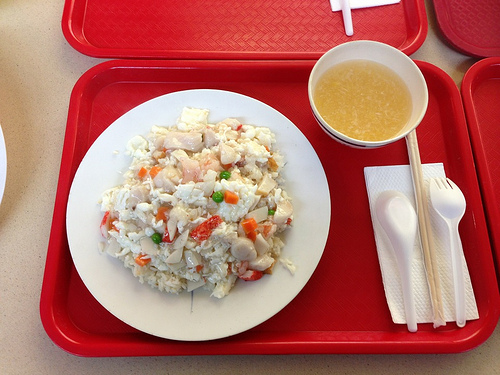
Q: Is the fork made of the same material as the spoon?
A: Yes, both the fork and the spoon are made of plastic.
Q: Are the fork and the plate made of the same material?
A: Yes, both the fork and the plate are made of plastic.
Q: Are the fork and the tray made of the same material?
A: Yes, both the fork and the tray are made of plastic.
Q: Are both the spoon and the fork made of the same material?
A: Yes, both the spoon and the fork are made of plastic.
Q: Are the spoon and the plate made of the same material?
A: Yes, both the spoon and the plate are made of plastic.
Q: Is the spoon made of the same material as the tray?
A: Yes, both the spoon and the tray are made of plastic.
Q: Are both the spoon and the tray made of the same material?
A: Yes, both the spoon and the tray are made of plastic.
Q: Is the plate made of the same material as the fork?
A: Yes, both the plate and the fork are made of plastic.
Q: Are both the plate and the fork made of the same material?
A: Yes, both the plate and the fork are made of plastic.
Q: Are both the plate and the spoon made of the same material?
A: Yes, both the plate and the spoon are made of plastic.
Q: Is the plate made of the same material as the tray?
A: Yes, both the plate and the tray are made of plastic.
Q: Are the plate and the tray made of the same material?
A: Yes, both the plate and the tray are made of plastic.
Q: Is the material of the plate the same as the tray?
A: Yes, both the plate and the tray are made of plastic.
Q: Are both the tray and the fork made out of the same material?
A: Yes, both the tray and the fork are made of plastic.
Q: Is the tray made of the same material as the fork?
A: Yes, both the tray and the fork are made of plastic.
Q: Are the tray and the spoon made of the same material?
A: Yes, both the tray and the spoon are made of plastic.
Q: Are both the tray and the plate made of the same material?
A: Yes, both the tray and the plate are made of plastic.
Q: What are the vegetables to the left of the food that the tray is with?
A: The vegetables are peas.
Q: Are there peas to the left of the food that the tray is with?
A: Yes, there are peas to the left of the food.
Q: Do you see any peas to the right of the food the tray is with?
A: No, the peas are to the left of the food.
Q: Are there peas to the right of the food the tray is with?
A: No, the peas are to the left of the food.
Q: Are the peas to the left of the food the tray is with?
A: Yes, the peas are to the left of the food.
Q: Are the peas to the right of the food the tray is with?
A: No, the peas are to the left of the food.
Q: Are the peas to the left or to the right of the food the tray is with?
A: The peas are to the left of the food.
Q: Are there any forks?
A: Yes, there is a fork.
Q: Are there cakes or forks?
A: Yes, there is a fork.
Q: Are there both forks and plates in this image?
A: Yes, there are both a fork and a plate.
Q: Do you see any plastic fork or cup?
A: Yes, there is a plastic fork.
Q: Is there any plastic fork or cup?
A: Yes, there is a plastic fork.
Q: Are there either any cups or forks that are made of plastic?
A: Yes, the fork is made of plastic.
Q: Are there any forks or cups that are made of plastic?
A: Yes, the fork is made of plastic.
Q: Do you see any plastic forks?
A: Yes, there is a fork that is made of plastic.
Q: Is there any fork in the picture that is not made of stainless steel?
A: Yes, there is a fork that is made of plastic.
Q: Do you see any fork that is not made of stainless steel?
A: Yes, there is a fork that is made of plastic.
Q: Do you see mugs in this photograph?
A: No, there are no mugs.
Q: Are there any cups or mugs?
A: No, there are no mugs or cups.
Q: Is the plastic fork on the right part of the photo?
A: Yes, the fork is on the right of the image.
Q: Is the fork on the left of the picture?
A: No, the fork is on the right of the image.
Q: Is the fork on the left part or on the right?
A: The fork is on the right of the image.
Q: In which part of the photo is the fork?
A: The fork is on the right of the image.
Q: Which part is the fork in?
A: The fork is on the right of the image.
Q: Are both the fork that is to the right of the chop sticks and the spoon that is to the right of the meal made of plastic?
A: Yes, both the fork and the spoon are made of plastic.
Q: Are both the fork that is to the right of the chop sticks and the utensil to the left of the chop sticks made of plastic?
A: Yes, both the fork and the spoon are made of plastic.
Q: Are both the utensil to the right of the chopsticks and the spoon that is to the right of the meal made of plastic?
A: Yes, both the fork and the spoon are made of plastic.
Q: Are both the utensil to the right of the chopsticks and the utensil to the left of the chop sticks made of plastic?
A: Yes, both the fork and the spoon are made of plastic.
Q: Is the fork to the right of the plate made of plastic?
A: Yes, the fork is made of plastic.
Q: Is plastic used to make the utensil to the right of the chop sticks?
A: Yes, the fork is made of plastic.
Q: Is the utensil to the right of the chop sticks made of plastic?
A: Yes, the fork is made of plastic.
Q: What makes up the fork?
A: The fork is made of plastic.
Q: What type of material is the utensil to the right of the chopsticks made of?
A: The fork is made of plastic.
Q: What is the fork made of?
A: The fork is made of plastic.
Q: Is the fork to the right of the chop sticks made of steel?
A: No, the fork is made of plastic.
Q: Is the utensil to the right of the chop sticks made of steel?
A: No, the fork is made of plastic.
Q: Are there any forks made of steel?
A: No, there is a fork but it is made of plastic.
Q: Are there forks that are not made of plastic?
A: No, there is a fork but it is made of plastic.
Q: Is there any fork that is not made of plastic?
A: No, there is a fork but it is made of plastic.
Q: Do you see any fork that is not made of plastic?
A: No, there is a fork but it is made of plastic.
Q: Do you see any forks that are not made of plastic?
A: No, there is a fork but it is made of plastic.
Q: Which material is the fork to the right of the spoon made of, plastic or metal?
A: The fork is made of plastic.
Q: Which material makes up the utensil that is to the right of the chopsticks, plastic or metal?
A: The fork is made of plastic.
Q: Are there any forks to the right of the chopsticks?
A: Yes, there is a fork to the right of the chopsticks.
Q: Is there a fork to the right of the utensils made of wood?
A: Yes, there is a fork to the right of the chopsticks.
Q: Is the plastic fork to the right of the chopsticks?
A: Yes, the fork is to the right of the chopsticks.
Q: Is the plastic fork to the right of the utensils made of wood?
A: Yes, the fork is to the right of the chopsticks.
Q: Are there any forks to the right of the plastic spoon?
A: Yes, there is a fork to the right of the spoon.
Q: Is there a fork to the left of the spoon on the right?
A: No, the fork is to the right of the spoon.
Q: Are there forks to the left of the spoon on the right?
A: No, the fork is to the right of the spoon.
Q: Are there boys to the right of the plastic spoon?
A: No, there is a fork to the right of the spoon.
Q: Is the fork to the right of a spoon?
A: Yes, the fork is to the right of a spoon.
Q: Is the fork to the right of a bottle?
A: No, the fork is to the right of a spoon.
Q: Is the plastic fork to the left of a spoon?
A: No, the fork is to the right of a spoon.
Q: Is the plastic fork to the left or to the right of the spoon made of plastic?
A: The fork is to the right of the spoon.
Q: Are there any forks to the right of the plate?
A: Yes, there is a fork to the right of the plate.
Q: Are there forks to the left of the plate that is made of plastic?
A: No, the fork is to the right of the plate.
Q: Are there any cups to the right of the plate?
A: No, there is a fork to the right of the plate.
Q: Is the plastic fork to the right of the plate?
A: Yes, the fork is to the right of the plate.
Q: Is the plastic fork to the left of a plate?
A: No, the fork is to the right of a plate.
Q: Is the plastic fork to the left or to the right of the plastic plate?
A: The fork is to the right of the plate.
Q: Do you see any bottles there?
A: No, there are no bottles.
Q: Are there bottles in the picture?
A: No, there are no bottles.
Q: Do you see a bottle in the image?
A: No, there are no bottles.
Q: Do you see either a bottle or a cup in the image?
A: No, there are no bottles or cups.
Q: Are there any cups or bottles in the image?
A: No, there are no bottles or cups.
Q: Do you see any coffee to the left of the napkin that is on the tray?
A: No, there is meal to the left of the napkin.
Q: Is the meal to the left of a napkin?
A: Yes, the meal is to the left of a napkin.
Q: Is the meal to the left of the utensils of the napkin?
A: Yes, the meal is to the left of the utensils.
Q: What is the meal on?
A: The meal is on the tray.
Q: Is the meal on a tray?
A: Yes, the meal is on a tray.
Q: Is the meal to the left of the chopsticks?
A: Yes, the meal is to the left of the chopsticks.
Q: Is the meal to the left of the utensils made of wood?
A: Yes, the meal is to the left of the chopsticks.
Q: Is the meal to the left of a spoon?
A: Yes, the meal is to the left of a spoon.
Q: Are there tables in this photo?
A: Yes, there is a table.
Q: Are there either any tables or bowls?
A: Yes, there is a table.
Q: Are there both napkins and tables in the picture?
A: Yes, there are both a table and a napkin.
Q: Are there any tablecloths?
A: No, there are no tablecloths.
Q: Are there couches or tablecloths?
A: No, there are no tablecloths or couches.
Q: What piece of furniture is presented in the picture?
A: The piece of furniture is a table.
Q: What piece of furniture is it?
A: The piece of furniture is a table.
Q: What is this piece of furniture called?
A: This is a table.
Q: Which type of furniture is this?
A: This is a table.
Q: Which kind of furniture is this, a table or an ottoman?
A: This is a table.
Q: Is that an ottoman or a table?
A: That is a table.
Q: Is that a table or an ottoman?
A: That is a table.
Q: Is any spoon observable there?
A: Yes, there is a spoon.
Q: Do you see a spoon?
A: Yes, there is a spoon.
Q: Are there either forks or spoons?
A: Yes, there is a spoon.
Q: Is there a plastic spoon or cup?
A: Yes, there is a plastic spoon.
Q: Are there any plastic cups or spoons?
A: Yes, there is a plastic spoon.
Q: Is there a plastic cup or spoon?
A: Yes, there is a plastic spoon.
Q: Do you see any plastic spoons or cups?
A: Yes, there is a plastic spoon.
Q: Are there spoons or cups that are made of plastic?
A: Yes, the spoon is made of plastic.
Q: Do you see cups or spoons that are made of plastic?
A: Yes, the spoon is made of plastic.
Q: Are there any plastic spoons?
A: Yes, there is a spoon that is made of plastic.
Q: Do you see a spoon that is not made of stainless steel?
A: Yes, there is a spoon that is made of plastic.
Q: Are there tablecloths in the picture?
A: No, there are no tablecloths.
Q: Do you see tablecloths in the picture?
A: No, there are no tablecloths.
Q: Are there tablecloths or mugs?
A: No, there are no tablecloths or mugs.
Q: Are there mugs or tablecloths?
A: No, there are no tablecloths or mugs.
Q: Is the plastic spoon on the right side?
A: Yes, the spoon is on the right of the image.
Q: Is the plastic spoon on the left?
A: No, the spoon is on the right of the image.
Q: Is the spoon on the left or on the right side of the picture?
A: The spoon is on the right of the image.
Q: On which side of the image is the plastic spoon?
A: The spoon is on the right of the image.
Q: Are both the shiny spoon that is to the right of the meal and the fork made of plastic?
A: Yes, both the spoon and the fork are made of plastic.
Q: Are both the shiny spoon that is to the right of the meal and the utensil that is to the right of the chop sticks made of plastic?
A: Yes, both the spoon and the fork are made of plastic.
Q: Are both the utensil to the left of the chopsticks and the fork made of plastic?
A: Yes, both the spoon and the fork are made of plastic.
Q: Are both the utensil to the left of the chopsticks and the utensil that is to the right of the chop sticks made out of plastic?
A: Yes, both the spoon and the fork are made of plastic.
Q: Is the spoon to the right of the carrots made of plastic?
A: Yes, the spoon is made of plastic.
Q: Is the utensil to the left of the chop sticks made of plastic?
A: Yes, the spoon is made of plastic.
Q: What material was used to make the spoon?
A: The spoon is made of plastic.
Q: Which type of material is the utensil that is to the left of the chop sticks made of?
A: The spoon is made of plastic.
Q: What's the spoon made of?
A: The spoon is made of plastic.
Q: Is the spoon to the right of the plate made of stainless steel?
A: No, the spoon is made of plastic.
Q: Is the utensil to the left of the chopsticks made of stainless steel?
A: No, the spoon is made of plastic.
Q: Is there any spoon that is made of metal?
A: No, there is a spoon but it is made of plastic.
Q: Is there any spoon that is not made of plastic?
A: No, there is a spoon but it is made of plastic.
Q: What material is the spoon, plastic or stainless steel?
A: The spoon is made of plastic.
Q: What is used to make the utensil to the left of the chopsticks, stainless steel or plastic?
A: The spoon is made of plastic.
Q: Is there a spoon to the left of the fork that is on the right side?
A: Yes, there is a spoon to the left of the fork.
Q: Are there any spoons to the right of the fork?
A: No, the spoon is to the left of the fork.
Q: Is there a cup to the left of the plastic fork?
A: No, there is a spoon to the left of the fork.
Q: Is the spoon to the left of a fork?
A: Yes, the spoon is to the left of a fork.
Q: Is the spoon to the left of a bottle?
A: No, the spoon is to the left of a fork.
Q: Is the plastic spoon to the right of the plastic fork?
A: No, the spoon is to the left of the fork.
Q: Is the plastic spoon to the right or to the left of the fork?
A: The spoon is to the left of the fork.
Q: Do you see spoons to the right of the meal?
A: Yes, there is a spoon to the right of the meal.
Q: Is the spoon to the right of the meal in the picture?
A: Yes, the spoon is to the right of the meal.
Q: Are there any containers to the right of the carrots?
A: No, there is a spoon to the right of the carrots.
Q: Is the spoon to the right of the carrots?
A: Yes, the spoon is to the right of the carrots.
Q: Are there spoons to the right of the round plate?
A: Yes, there is a spoon to the right of the plate.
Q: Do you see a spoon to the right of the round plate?
A: Yes, there is a spoon to the right of the plate.